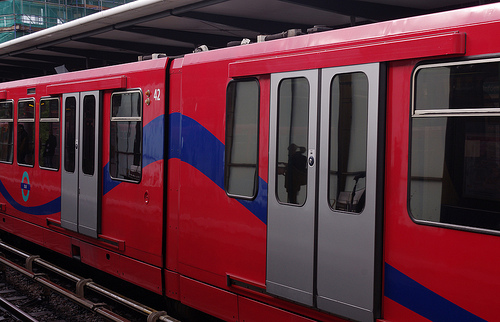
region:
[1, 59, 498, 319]
the train is red and blue.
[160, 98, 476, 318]
blue stripe on the train.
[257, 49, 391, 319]
the doors are silver.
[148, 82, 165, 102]
white number on the train.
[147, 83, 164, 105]
train is number 42.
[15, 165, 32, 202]
the logo is a circle.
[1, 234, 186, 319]
train is on a track.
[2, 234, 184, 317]
the track is brown.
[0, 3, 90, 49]
the ceiling is green.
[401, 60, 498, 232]
the window looks black.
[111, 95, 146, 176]
window on the train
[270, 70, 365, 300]
the door on the train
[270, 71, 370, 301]
the door is grey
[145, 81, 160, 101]
number on the train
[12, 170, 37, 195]
logo on the train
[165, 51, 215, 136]
train is red and blue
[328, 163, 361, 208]
a reflection on the window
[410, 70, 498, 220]
the window is black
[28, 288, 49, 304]
small rocks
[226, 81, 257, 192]
a window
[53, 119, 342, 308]
this is a train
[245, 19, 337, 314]
this is a door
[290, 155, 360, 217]
this is a window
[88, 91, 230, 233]
the train is red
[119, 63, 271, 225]
the train is metal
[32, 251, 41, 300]
this is a rail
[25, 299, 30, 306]
this is a track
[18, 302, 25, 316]
the track is metal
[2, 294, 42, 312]
the track has rust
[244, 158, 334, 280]
the door is silver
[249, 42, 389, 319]
silver doors on the side of a red train.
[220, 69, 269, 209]
a window on the side of a train.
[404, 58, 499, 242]
A window on a train car.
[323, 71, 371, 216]
a small window on a train car door.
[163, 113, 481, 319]
a blue stripe on a train car.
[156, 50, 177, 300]
a division between two train cars.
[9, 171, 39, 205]
a seal on teh side of a train car.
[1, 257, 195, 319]
the bottom of a train.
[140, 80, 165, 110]
the number 42 on a train.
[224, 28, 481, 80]
a bar over a train door.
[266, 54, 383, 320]
the grey double doors of the train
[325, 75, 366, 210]
the window on the train door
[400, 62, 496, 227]
the window on the side of the train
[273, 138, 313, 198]
the persons reflection in the window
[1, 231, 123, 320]
the tracks under the train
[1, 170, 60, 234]
the blue stripe on the red train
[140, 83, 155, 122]
the round lights on the side of the train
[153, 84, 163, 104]
the number on the side of the train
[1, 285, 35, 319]
the railroad on the ground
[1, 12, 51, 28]
the guard rail above the platform canopy